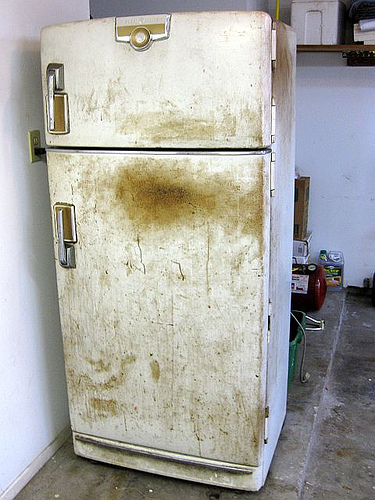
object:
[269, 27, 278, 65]
hinge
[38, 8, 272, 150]
door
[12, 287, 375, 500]
floor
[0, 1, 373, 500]
room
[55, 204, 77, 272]
handle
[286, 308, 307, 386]
basket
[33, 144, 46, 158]
power cord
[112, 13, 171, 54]
logo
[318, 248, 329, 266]
bottle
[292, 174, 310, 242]
cardboard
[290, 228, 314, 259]
box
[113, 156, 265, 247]
dirt spot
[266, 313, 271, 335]
hinge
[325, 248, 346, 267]
chemical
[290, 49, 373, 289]
wall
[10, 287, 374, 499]
concrete ground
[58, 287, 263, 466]
dirty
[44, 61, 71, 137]
handle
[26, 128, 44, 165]
plug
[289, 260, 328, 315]
pump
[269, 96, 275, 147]
hinge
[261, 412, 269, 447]
hinge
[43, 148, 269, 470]
door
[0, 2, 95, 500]
wall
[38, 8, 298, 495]
fridge